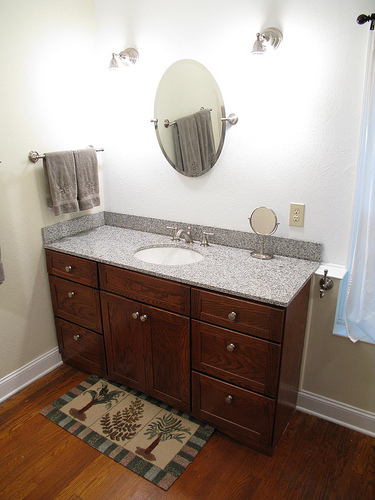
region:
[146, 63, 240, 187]
a round mirror on the wall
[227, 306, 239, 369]
silver knobs on the cabinet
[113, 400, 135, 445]
a leaf pattern on the rug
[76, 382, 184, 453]
a rug on the floor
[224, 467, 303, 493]
wooden covering the floor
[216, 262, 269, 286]
a gray granite countertop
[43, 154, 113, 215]
beige towels hanging on a rack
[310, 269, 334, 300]
a metal cylinder in the wall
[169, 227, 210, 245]
a chrome faucet and handles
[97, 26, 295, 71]
lights shining above the sink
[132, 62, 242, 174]
a mirror hanging on a wall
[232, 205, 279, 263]
a mirror placed on a counter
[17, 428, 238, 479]
a rug on the floor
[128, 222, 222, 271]
a bathroom sink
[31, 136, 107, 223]
two towels hanging on a rack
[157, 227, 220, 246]
a bathroom faucet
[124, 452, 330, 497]
a wooden floor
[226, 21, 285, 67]
a light mounted to the wall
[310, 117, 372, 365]
a window with a white curtain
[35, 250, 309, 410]
a bathroom vanity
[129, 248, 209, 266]
this is a sink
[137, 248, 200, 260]
the sink is white in color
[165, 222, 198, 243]
the tap is closed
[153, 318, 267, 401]
the cupboards are closed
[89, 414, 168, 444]
this is a floor mat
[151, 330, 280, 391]
the cupboards are wooden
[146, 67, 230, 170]
the wall mirror is wide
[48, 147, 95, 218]
the towels are on the holder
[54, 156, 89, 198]
the towels are grey in color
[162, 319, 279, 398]
the cupboards are brown in color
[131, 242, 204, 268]
Sink in a bathroom.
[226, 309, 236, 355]
Two silver knobs on drawers.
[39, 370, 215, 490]
Decorative rug on the bathroom floor.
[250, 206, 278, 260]
Silver mirror on the counter.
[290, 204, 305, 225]
Outlet on the wall.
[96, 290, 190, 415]
Double doors on a bathroom vanity.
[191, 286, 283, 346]
Wooden drawer of bathroom vanity.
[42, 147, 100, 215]
Two gray hand towels.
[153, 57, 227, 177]
Oval mirror on the wall.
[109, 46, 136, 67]
Silver light fixture on the wall.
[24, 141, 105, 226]
two small hand towels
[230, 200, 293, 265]
silver makeup mirror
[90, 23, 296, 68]
two silver bathroom lights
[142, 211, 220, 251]
silver faucet accessories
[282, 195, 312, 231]
cream color electrical outlet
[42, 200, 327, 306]
gray bathroom counter top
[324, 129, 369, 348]
white shear bathroom window curtin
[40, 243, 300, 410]
nice wooden bathroom cabinet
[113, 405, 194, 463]
palm tree on a bathroom rug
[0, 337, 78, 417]
bright white baseboards